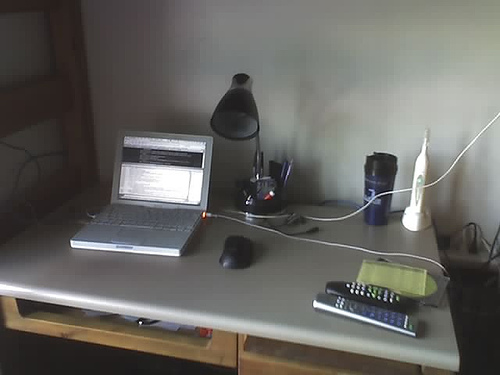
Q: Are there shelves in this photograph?
A: No, there are no shelves.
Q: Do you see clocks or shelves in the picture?
A: No, there are no shelves or clocks.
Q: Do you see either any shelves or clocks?
A: No, there are no shelves or clocks.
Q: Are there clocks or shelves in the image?
A: No, there are no shelves or clocks.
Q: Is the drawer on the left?
A: Yes, the drawer is on the left of the image.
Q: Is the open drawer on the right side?
A: No, the drawer is on the left of the image.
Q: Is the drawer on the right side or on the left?
A: The drawer is on the left of the image.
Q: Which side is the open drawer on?
A: The drawer is on the left of the image.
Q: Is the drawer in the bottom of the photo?
A: Yes, the drawer is in the bottom of the image.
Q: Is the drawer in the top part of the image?
A: No, the drawer is in the bottom of the image.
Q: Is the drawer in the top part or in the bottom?
A: The drawer is in the bottom of the image.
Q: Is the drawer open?
A: Yes, the drawer is open.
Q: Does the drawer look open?
A: Yes, the drawer is open.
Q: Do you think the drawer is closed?
A: No, the drawer is open.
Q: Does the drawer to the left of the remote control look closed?
A: No, the drawer is open.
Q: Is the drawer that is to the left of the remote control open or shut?
A: The drawer is open.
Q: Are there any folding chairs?
A: No, there are no folding chairs.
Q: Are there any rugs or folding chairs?
A: No, there are no folding chairs or rugs.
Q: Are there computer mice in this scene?
A: Yes, there is a computer mouse.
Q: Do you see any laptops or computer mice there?
A: Yes, there is a computer mouse.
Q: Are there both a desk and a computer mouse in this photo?
A: Yes, there are both a computer mouse and a desk.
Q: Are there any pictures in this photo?
A: No, there are no pictures.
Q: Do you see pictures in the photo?
A: No, there are no pictures.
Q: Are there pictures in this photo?
A: No, there are no pictures.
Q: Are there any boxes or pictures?
A: No, there are no pictures or boxes.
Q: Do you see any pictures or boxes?
A: No, there are no pictures or boxes.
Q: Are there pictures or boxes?
A: No, there are no pictures or boxes.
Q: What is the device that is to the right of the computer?
A: The device is a computer mouse.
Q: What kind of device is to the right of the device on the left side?
A: The device is a computer mouse.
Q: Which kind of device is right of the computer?
A: The device is a computer mouse.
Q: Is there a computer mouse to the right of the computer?
A: Yes, there is a computer mouse to the right of the computer.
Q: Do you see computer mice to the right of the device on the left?
A: Yes, there is a computer mouse to the right of the computer.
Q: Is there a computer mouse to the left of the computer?
A: No, the computer mouse is to the right of the computer.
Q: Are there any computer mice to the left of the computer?
A: No, the computer mouse is to the right of the computer.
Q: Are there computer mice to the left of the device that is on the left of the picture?
A: No, the computer mouse is to the right of the computer.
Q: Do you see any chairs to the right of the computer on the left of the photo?
A: No, there is a computer mouse to the right of the computer.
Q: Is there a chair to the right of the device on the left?
A: No, there is a computer mouse to the right of the computer.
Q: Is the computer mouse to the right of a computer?
A: Yes, the computer mouse is to the right of a computer.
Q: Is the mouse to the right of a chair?
A: No, the mouse is to the right of a computer.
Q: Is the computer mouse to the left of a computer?
A: No, the computer mouse is to the right of a computer.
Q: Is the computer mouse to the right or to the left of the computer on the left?
A: The computer mouse is to the right of the computer.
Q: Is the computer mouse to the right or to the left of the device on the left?
A: The computer mouse is to the right of the computer.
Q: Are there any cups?
A: Yes, there is a cup.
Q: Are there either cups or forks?
A: Yes, there is a cup.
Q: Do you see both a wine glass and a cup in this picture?
A: No, there is a cup but no wine glasses.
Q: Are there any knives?
A: No, there are no knives.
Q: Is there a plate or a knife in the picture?
A: No, there are no knives or plates.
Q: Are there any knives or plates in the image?
A: No, there are no knives or plates.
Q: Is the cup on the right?
A: Yes, the cup is on the right of the image.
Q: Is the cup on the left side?
A: No, the cup is on the right of the image.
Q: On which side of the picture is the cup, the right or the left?
A: The cup is on the right of the image.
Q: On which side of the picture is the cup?
A: The cup is on the right of the image.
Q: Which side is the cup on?
A: The cup is on the right of the image.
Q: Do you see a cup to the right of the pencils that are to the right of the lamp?
A: Yes, there is a cup to the right of the pencils.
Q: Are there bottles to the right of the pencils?
A: No, there is a cup to the right of the pencils.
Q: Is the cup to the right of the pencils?
A: Yes, the cup is to the right of the pencils.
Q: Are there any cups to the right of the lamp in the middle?
A: Yes, there is a cup to the right of the lamp.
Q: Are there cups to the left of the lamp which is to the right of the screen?
A: No, the cup is to the right of the lamp.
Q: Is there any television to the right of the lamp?
A: No, there is a cup to the right of the lamp.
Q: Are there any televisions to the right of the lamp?
A: No, there is a cup to the right of the lamp.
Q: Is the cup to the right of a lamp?
A: Yes, the cup is to the right of a lamp.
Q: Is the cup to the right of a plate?
A: No, the cup is to the right of a lamp.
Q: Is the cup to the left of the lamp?
A: No, the cup is to the right of the lamp.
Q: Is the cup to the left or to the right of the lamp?
A: The cup is to the right of the lamp.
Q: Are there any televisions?
A: No, there are no televisions.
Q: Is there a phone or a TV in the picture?
A: No, there are no televisions or phones.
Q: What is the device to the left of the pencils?
A: The device is a screen.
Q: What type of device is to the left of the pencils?
A: The device is a screen.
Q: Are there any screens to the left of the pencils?
A: Yes, there is a screen to the left of the pencils.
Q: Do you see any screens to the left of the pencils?
A: Yes, there is a screen to the left of the pencils.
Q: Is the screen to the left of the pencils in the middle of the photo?
A: Yes, the screen is to the left of the pencils.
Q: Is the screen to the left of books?
A: No, the screen is to the left of the pencils.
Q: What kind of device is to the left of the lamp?
A: The device is a screen.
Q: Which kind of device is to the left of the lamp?
A: The device is a screen.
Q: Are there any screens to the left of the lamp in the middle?
A: Yes, there is a screen to the left of the lamp.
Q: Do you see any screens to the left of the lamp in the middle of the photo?
A: Yes, there is a screen to the left of the lamp.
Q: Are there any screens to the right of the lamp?
A: No, the screen is to the left of the lamp.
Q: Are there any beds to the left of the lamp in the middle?
A: No, there is a screen to the left of the lamp.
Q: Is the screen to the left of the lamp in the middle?
A: Yes, the screen is to the left of the lamp.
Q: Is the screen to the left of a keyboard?
A: No, the screen is to the left of the lamp.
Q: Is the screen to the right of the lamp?
A: No, the screen is to the left of the lamp.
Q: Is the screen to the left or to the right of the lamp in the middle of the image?
A: The screen is to the left of the lamp.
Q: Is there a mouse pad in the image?
A: No, there are no mouse pads.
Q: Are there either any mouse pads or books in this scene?
A: No, there are no mouse pads or books.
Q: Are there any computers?
A: Yes, there is a computer.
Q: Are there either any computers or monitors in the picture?
A: Yes, there is a computer.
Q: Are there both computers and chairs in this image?
A: No, there is a computer but no chairs.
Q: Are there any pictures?
A: No, there are no pictures.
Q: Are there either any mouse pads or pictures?
A: No, there are no pictures or mouse pads.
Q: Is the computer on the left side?
A: Yes, the computer is on the left of the image.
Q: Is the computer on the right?
A: No, the computer is on the left of the image.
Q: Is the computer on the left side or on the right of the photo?
A: The computer is on the left of the image.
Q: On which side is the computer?
A: The computer is on the left of the image.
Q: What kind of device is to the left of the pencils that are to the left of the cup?
A: The device is a computer.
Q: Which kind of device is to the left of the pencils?
A: The device is a computer.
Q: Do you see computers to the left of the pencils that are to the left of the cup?
A: Yes, there is a computer to the left of the pencils.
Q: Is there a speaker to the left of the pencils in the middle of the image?
A: No, there is a computer to the left of the pencils.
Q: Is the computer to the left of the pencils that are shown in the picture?
A: Yes, the computer is to the left of the pencils.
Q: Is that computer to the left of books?
A: No, the computer is to the left of the pencils.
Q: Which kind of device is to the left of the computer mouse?
A: The device is a computer.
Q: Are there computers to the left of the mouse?
A: Yes, there is a computer to the left of the mouse.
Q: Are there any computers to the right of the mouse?
A: No, the computer is to the left of the mouse.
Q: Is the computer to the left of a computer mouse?
A: Yes, the computer is to the left of a computer mouse.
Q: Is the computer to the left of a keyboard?
A: No, the computer is to the left of a computer mouse.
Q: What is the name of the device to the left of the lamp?
A: The device is a computer.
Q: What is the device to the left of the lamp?
A: The device is a computer.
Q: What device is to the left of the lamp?
A: The device is a computer.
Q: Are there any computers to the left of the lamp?
A: Yes, there is a computer to the left of the lamp.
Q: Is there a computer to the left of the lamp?
A: Yes, there is a computer to the left of the lamp.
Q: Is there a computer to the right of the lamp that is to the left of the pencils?
A: No, the computer is to the left of the lamp.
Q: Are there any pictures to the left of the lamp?
A: No, there is a computer to the left of the lamp.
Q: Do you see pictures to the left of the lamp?
A: No, there is a computer to the left of the lamp.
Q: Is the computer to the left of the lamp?
A: Yes, the computer is to the left of the lamp.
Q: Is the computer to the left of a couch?
A: No, the computer is to the left of the lamp.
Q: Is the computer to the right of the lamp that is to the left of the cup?
A: No, the computer is to the left of the lamp.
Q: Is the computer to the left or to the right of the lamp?
A: The computer is to the left of the lamp.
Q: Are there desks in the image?
A: Yes, there is a desk.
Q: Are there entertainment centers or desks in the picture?
A: Yes, there is a desk.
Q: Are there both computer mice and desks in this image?
A: Yes, there are both a desk and a computer mouse.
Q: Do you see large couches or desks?
A: Yes, there is a large desk.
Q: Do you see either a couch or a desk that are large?
A: Yes, the desk is large.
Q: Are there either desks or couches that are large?
A: Yes, the desk is large.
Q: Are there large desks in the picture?
A: Yes, there is a large desk.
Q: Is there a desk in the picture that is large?
A: Yes, there is a desk that is large.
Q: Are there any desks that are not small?
A: Yes, there is a large desk.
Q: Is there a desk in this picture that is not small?
A: Yes, there is a large desk.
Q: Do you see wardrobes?
A: No, there are no wardrobes.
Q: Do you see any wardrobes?
A: No, there are no wardrobes.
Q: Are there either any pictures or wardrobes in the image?
A: No, there are no wardrobes or pictures.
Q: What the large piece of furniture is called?
A: The piece of furniture is a desk.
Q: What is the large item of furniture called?
A: The piece of furniture is a desk.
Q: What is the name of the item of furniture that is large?
A: The piece of furniture is a desk.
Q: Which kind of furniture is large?
A: The furniture is a desk.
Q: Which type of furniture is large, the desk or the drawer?
A: The desk is large.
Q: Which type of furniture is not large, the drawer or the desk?
A: The drawer is not large.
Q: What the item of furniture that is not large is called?
A: The piece of furniture is a drawer.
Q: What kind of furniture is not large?
A: The furniture is a drawer.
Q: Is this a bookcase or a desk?
A: This is a desk.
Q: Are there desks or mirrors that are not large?
A: No, there is a desk but it is large.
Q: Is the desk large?
A: Yes, the desk is large.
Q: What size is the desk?
A: The desk is large.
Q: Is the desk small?
A: No, the desk is large.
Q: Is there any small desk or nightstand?
A: No, there is a desk but it is large.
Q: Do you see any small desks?
A: No, there is a desk but it is large.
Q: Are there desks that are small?
A: No, there is a desk but it is large.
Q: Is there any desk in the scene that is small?
A: No, there is a desk but it is large.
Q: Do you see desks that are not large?
A: No, there is a desk but it is large.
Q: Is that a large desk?
A: Yes, that is a large desk.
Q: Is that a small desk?
A: No, that is a large desk.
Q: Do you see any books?
A: No, there are no books.